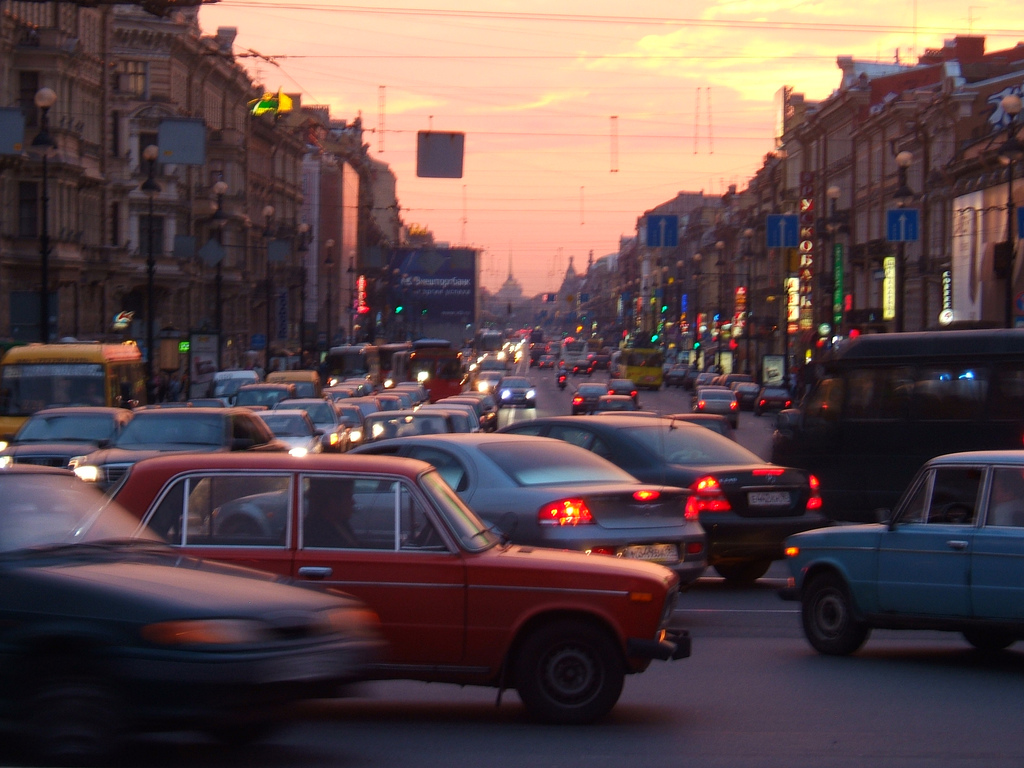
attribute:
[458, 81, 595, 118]
cloud — white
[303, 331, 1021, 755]
road — gray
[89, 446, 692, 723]
car — red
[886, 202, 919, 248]
banner — blue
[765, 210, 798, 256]
banner — blue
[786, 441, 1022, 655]
car — blue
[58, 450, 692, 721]
sedan — red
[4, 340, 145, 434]
truck — yellow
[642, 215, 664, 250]
banner — blue, small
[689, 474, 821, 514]
taillights — red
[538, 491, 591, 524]
taillight — red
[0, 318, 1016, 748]
traffic — heavy